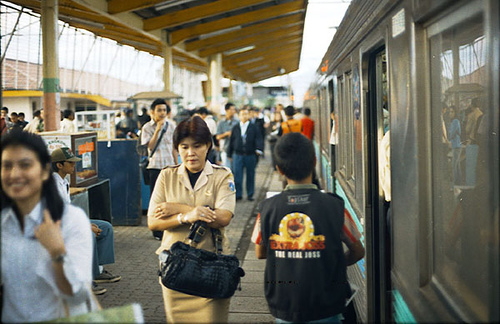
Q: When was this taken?
A: During the day.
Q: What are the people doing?
A: Getting on or off the train.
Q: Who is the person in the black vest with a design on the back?
A: A child.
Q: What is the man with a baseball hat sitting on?
A: A bench.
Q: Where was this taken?
A: At a train station.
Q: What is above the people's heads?
A: The roof.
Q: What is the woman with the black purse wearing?
A: A khaki dress.